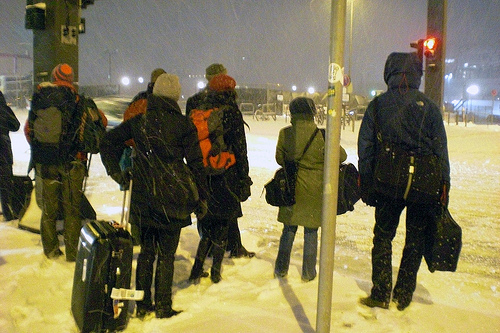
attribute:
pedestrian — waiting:
[260, 93, 350, 235]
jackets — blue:
[45, 34, 457, 283]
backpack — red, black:
[187, 110, 235, 176]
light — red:
[420, 34, 437, 56]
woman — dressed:
[107, 69, 217, 325]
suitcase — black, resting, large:
[64, 166, 144, 333]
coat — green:
[93, 91, 204, 233]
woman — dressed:
[248, 87, 359, 294]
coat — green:
[259, 116, 349, 235]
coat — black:
[348, 47, 464, 214]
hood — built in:
[374, 53, 429, 92]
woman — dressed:
[168, 74, 260, 287]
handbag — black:
[256, 155, 304, 213]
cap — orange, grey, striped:
[45, 57, 79, 90]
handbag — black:
[139, 109, 211, 226]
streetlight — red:
[418, 28, 447, 78]